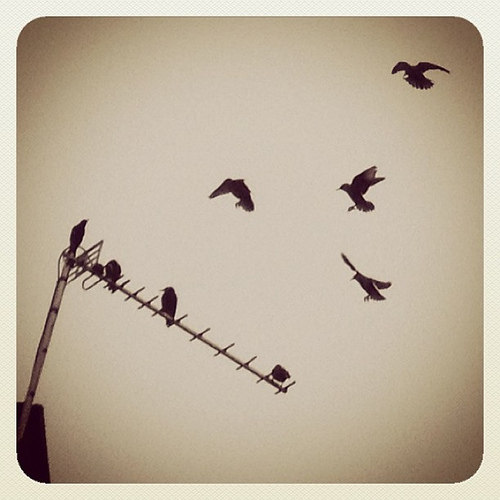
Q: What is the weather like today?
A: It is cloudless.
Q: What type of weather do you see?
A: It is cloudless.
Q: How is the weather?
A: It is cloudless.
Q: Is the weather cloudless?
A: Yes, it is cloudless.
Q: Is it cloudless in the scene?
A: Yes, it is cloudless.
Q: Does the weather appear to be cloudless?
A: Yes, it is cloudless.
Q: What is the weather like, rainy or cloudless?
A: It is cloudless.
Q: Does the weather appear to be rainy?
A: No, it is cloudless.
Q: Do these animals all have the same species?
A: Yes, all the animals are birds.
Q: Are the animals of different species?
A: No, all the animals are birds.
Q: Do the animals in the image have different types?
A: No, all the animals are birds.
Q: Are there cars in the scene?
A: No, there are no cars.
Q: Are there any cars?
A: No, there are no cars.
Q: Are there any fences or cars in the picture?
A: No, there are no cars or fences.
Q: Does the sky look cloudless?
A: Yes, the sky is cloudless.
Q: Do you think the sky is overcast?
A: No, the sky is cloudless.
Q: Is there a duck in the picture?
A: No, there are no ducks.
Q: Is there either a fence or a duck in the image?
A: No, there are no ducks or fences.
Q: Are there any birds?
A: Yes, there is a bird.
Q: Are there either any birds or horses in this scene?
A: Yes, there is a bird.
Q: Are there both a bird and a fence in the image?
A: No, there is a bird but no fences.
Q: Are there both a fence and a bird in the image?
A: No, there is a bird but no fences.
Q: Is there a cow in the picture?
A: No, there are no cows.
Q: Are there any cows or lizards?
A: No, there are no cows or lizards.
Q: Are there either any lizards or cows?
A: No, there are no cows or lizards.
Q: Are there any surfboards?
A: No, there are no surfboards.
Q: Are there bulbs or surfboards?
A: No, there are no surfboards or bulbs.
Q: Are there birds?
A: Yes, there are birds.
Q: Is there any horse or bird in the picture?
A: Yes, there are birds.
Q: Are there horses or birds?
A: Yes, there are birds.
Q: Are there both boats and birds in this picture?
A: No, there are birds but no boats.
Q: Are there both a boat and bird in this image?
A: No, there are birds but no boats.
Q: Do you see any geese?
A: No, there are no geese.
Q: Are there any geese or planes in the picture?
A: No, there are no geese or planes.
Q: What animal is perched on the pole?
A: The birds are perched on the pole.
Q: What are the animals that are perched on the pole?
A: The animals are birds.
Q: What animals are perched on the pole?
A: The animals are birds.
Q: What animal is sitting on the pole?
A: The birds are sitting on the pole.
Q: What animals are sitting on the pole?
A: The animals are birds.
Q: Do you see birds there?
A: Yes, there is a bird.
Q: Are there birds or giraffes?
A: Yes, there is a bird.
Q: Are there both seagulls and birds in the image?
A: No, there is a bird but no seagulls.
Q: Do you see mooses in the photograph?
A: No, there are no mooses.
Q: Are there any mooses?
A: No, there are no mooses.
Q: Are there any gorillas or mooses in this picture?
A: No, there are no mooses or gorillas.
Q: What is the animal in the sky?
A: The animal is a bird.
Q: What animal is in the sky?
A: The animal is a bird.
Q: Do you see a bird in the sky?
A: Yes, there is a bird in the sky.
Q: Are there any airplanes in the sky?
A: No, there is a bird in the sky.